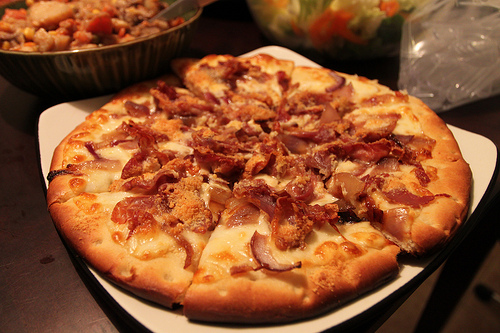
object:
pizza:
[48, 51, 476, 329]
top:
[110, 76, 432, 239]